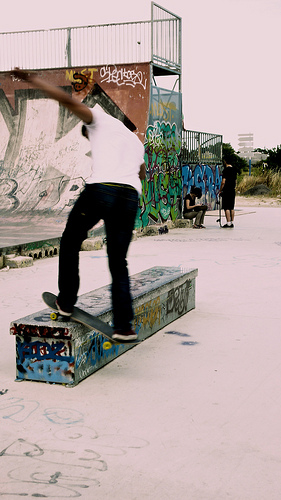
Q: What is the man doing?
A: Skateboarding.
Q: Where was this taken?
A: A skateboard park.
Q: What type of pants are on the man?
A: Jeans.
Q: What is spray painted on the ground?
A: Graffiti.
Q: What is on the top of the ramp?
A: Guard rail.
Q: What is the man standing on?
A: Skateboard.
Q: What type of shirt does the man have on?
A: T-shirt.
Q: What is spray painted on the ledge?
A: Graffiti.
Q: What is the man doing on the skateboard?
A: Stunt.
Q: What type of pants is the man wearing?
A: Jeans.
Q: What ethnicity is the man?
A: Black.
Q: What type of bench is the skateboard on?
A: Cement.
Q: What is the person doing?
A: Skateboarding.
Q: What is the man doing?
A: Skateboarding.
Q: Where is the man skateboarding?
A: In a skatepark.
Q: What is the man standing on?
A: A skateboard.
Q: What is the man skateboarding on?
A: A bench.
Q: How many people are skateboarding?
A: One.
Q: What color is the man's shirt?
A: White.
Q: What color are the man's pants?
A: Black.